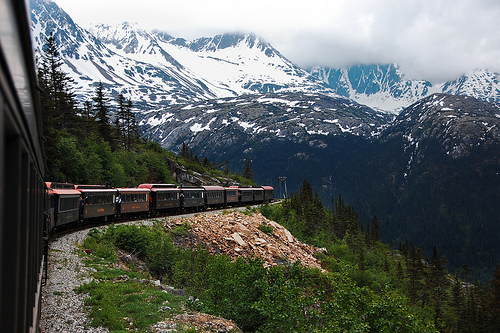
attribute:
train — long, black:
[51, 177, 271, 210]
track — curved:
[63, 200, 277, 231]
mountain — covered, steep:
[99, 126, 428, 332]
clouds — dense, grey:
[100, 2, 499, 58]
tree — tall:
[43, 32, 76, 147]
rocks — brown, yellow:
[200, 218, 326, 280]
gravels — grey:
[47, 244, 88, 331]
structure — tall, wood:
[277, 170, 293, 203]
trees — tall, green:
[115, 91, 139, 140]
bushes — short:
[114, 149, 166, 179]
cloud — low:
[293, 34, 497, 90]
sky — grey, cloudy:
[56, 1, 499, 80]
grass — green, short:
[88, 236, 154, 329]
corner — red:
[145, 183, 155, 203]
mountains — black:
[31, 2, 291, 77]